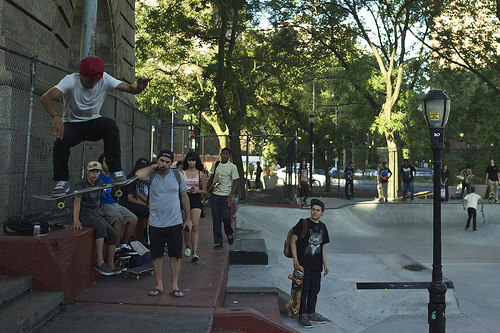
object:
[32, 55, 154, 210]
boy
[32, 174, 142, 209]
skateboard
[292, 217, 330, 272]
teeshirt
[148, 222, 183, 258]
shorts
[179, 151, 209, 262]
girl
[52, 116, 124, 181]
pants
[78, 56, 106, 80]
cap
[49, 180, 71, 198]
sneakers